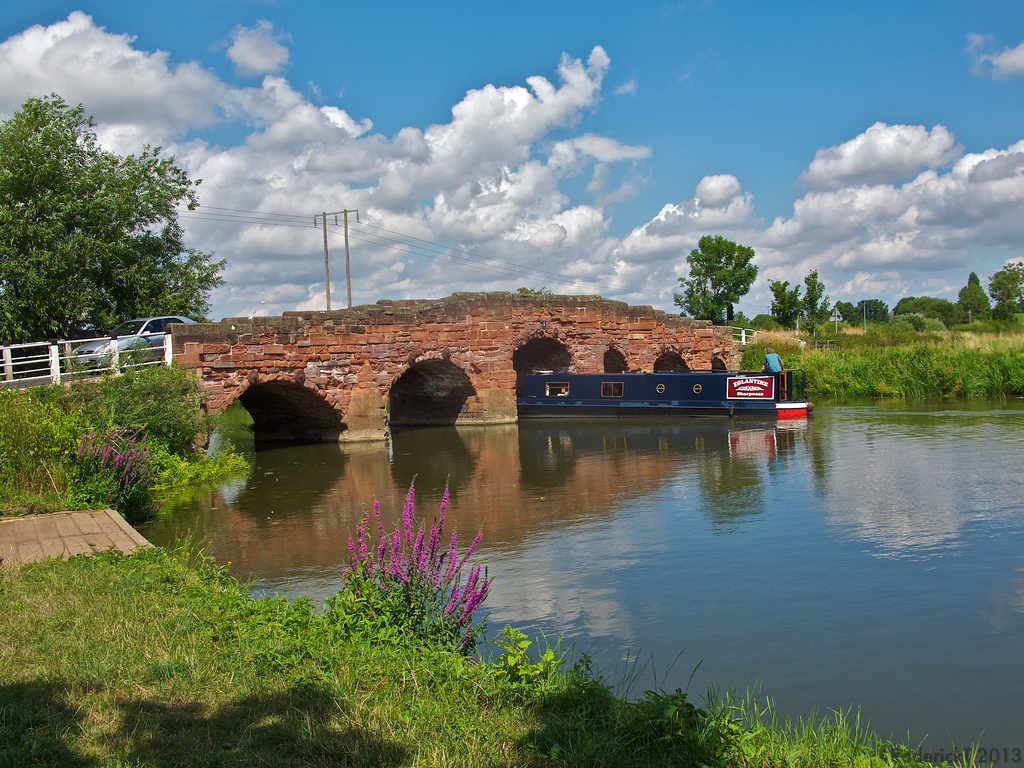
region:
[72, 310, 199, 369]
A car on a bridge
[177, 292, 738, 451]
A bridge over water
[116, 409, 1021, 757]
Water in a river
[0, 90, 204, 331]
A green tree near a bridge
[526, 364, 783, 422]
A boat in the water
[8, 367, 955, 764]
Grass beside a river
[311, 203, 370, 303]
Telephone poles behind a bridge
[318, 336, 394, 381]
Rocks on the side of a bridge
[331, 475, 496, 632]
Purple plants beside a river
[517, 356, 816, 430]
Boat going under the overpass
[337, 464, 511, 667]
Purple flowers near the river bank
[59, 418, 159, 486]
Purple flowers near the river bank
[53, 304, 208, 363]
Car driving over the bridge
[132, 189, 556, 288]
electric wire on the pole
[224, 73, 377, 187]
clouds over the bridge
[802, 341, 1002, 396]
tall grass at the river bank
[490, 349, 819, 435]
THE BARGE IS BLUE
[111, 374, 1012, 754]
THE WATER IS REFLECTING THE SKY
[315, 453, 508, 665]
THE FLOWERS ARE PURPLE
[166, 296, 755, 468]
THE BRIDGE GOES OVER THE WATER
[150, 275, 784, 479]
THE BRIDGE IS BRICK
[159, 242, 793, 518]
THE BRIDGE IS OLD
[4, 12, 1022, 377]
THE CLOUDS ARE PUFFY AND WHITE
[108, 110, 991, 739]
this is a park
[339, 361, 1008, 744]
this is a body of water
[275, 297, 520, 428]
this is a bridge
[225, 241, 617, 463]
the bridge is red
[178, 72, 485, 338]
the clouds are fluffy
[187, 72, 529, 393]
the clouds are white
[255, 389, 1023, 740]
the water is green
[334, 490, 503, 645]
purple flowers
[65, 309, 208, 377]
a light blue car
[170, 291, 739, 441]
a brown and red bridge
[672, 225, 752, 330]
a green tree in the distance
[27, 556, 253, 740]
a grassy area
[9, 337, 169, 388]
white railing next to the road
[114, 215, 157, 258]
green leaves on the tree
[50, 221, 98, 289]
green leaves on the tree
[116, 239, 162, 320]
green leaves on the tree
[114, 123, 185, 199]
green leaves on the tree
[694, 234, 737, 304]
green leaves on the tree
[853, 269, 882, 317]
green leaves on the tree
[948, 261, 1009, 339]
green leaves on the tree